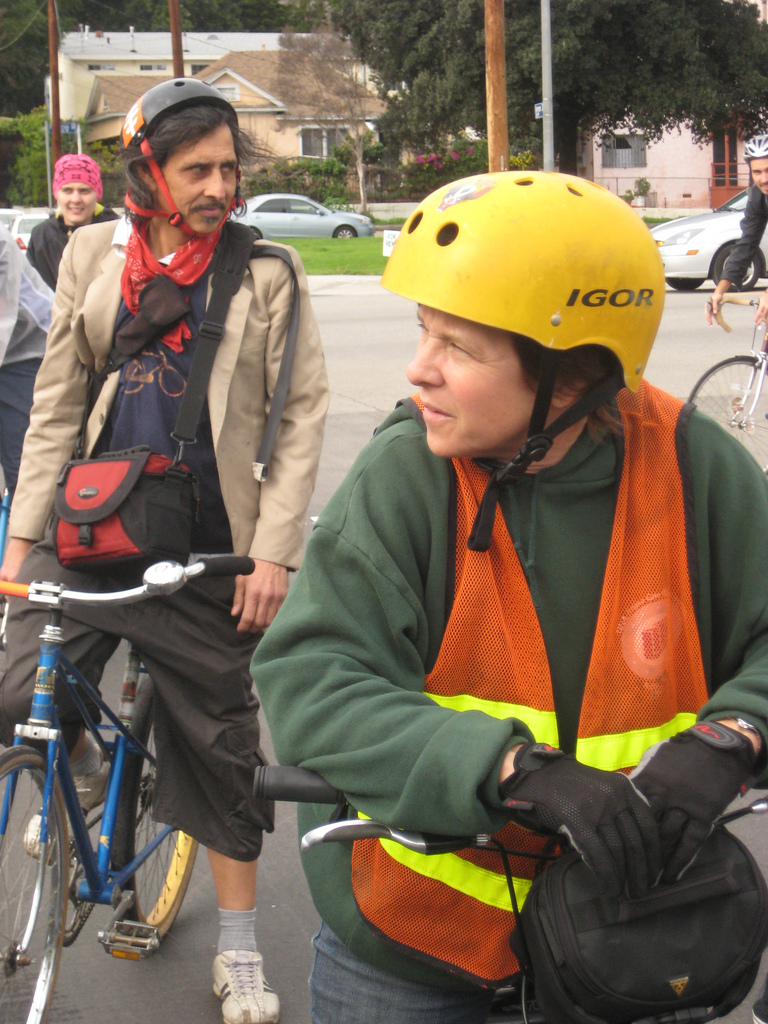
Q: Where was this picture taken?
A: On a street.